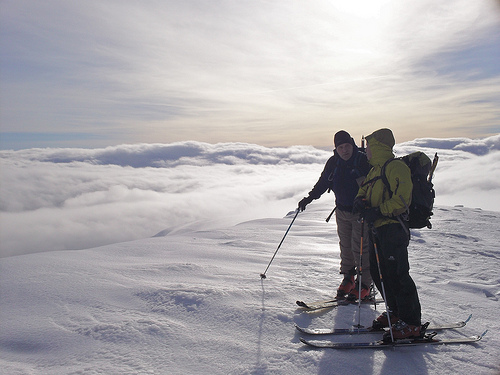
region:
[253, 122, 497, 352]
Two people on skis.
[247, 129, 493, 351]
Two skiers.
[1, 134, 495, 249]
The clouds are below the skiers.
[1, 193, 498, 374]
The skiers stand at the edge of a cliff.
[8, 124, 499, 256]
Clouds are seen beyond the cliff.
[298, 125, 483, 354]
The man in the yellow jacket is wearing a backpack.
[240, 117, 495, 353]
The men are standing on snowy ground.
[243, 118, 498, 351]
The two men are talking.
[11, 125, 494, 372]
The sun is reflecting on the snow and clouds.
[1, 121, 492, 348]
two skiers at what looks like the edge of the world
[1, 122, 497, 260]
these two skiers are above the cloud line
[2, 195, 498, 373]
two skiers are at the edge of a dropoff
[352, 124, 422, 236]
skier on the right is wearing a green ski jacket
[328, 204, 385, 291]
skier on the left is wearing light colored ski pants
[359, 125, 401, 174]
skier on the right is wearing his hood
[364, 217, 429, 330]
skier on the right is wearing dark ski pants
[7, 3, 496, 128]
the sky is cloudy but bright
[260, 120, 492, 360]
two skiers standing on the snow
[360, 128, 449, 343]
skier wearing yellow jacket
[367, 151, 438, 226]
black backpack skier is wearing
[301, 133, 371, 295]
skier wearing dark colored coat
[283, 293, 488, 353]
two sets of skis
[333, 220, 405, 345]
white and orange ski poles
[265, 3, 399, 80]
sun shining through the clouds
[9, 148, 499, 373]
snow covered mountain the skiers are on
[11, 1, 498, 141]
clouds spreading across the sky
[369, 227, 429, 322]
black pants skier is wearing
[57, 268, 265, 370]
PART OF THE SNOW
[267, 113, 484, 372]
TWO PEOPLE WITH SKIS ON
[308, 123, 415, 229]
PEOPLE WEARING HATS AND COATS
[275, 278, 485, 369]
TWO PAIR OF SKIS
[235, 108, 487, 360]
TWO PEOPLE WITH SKI POLES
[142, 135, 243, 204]
PART OF A CLOUDY SKY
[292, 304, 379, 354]
PART OF A PAIR OF SKIS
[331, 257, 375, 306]
PERSON WITH ORANGE BOOTS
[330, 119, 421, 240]
PERSON WITH GREEN COAT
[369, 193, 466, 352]
PERSON WITH BLACK PANTS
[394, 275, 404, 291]
man wearing black pants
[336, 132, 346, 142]
man wearing black hat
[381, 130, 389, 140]
man wearing grey hat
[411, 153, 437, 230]
black bookbag on mans back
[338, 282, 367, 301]
man wearing orange sneakers